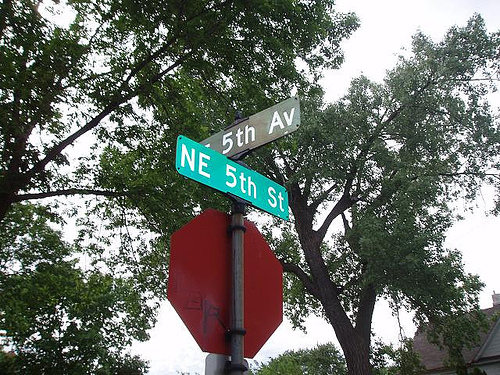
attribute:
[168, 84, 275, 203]
sign — green, metal, faded, painted, grey, red, bottom, atop, white, dark, lettering, rectangular, posted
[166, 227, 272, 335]
sign — stop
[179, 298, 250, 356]
graffiti — black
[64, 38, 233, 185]
branches — large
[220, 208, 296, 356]
signs — together, attached, mounted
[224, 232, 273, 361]
pole — metal, black, silver, straight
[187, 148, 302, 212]
lettering — white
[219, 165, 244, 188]
number — five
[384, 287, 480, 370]
home — across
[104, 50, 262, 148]
trees — big, along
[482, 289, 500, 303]
bucket — white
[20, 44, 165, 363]
tree — large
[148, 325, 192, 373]
sky — white